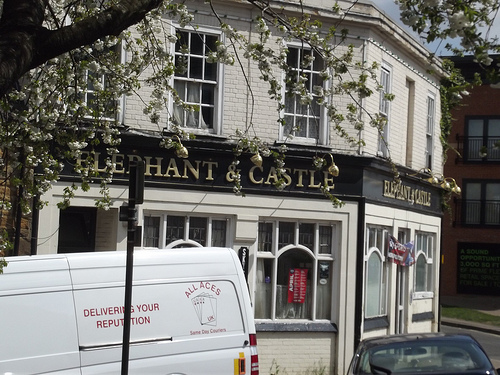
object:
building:
[0, 0, 459, 375]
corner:
[278, 306, 486, 375]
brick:
[231, 97, 240, 103]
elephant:
[73, 146, 220, 181]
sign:
[67, 139, 340, 194]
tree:
[0, 0, 393, 217]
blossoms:
[92, 75, 105, 95]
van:
[0, 238, 269, 375]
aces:
[199, 279, 221, 296]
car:
[342, 322, 500, 374]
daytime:
[383, 2, 459, 55]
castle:
[248, 159, 341, 191]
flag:
[385, 230, 421, 267]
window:
[362, 220, 395, 334]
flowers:
[158, 137, 174, 151]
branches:
[119, 77, 162, 139]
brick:
[455, 167, 464, 175]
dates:
[286, 266, 309, 307]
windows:
[172, 26, 230, 143]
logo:
[181, 277, 232, 339]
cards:
[200, 295, 219, 326]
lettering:
[198, 157, 223, 181]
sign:
[284, 266, 310, 308]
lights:
[427, 174, 440, 186]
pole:
[117, 159, 143, 371]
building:
[442, 51, 500, 308]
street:
[428, 312, 499, 366]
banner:
[361, 220, 445, 271]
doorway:
[389, 262, 408, 340]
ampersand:
[226, 163, 241, 183]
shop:
[53, 193, 442, 352]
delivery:
[82, 305, 136, 318]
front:
[359, 14, 443, 345]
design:
[182, 277, 226, 338]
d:
[83, 308, 90, 318]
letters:
[198, 279, 206, 290]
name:
[239, 242, 249, 281]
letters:
[242, 247, 248, 256]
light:
[243, 327, 263, 374]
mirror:
[404, 342, 429, 357]